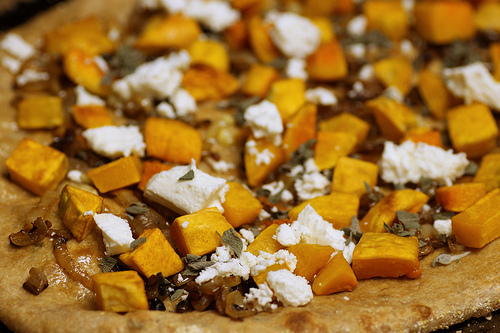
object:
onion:
[51, 234, 95, 295]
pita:
[3, 3, 499, 332]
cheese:
[312, 252, 357, 298]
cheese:
[378, 137, 468, 187]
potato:
[118, 225, 186, 277]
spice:
[217, 226, 246, 258]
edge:
[357, 267, 495, 331]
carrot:
[89, 155, 144, 194]